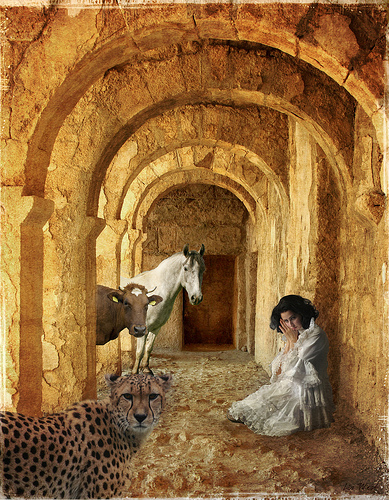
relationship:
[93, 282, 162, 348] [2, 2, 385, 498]
cow in painting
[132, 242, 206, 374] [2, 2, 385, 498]
horse and painting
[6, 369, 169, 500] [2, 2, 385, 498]
leopard in painting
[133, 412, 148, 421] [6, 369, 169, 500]
nose of leopard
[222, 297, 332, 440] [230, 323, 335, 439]
lady wearing dress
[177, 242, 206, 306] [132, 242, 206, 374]
head of horse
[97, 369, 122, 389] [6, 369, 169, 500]
ear of leopard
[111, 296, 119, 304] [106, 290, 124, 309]
tag in ear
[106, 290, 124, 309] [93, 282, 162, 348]
ear of cow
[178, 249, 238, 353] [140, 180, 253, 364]
opening in back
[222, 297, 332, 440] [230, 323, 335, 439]
lady in dress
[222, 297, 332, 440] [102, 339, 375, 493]
lady in dirt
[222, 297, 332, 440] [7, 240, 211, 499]
lady with animals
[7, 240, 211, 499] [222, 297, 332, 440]
animals with lady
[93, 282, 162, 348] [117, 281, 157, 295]
cow has horns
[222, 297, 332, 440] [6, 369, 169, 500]
lady with leopard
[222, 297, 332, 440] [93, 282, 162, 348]
lady with cow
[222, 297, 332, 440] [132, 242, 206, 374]
lady with horse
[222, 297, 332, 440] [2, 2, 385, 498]
lady in painting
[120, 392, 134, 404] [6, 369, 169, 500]
eye of leopard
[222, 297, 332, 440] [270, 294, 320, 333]
lady has hair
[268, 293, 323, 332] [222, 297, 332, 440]
head of lady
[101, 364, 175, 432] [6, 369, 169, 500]
head of leopard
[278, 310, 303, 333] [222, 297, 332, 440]
face of lady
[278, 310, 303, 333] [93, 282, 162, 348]
face of cow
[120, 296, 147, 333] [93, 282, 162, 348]
face of cow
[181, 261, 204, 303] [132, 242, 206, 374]
face of horse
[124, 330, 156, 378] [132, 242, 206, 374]
legs of horse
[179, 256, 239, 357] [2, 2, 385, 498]
door in painting